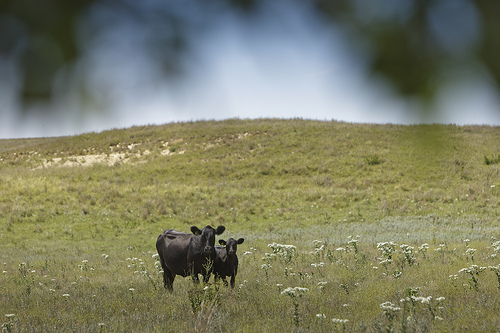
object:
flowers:
[377, 301, 394, 309]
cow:
[214, 237, 245, 290]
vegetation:
[0, 1, 500, 185]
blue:
[273, 6, 310, 27]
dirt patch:
[36, 150, 150, 170]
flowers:
[398, 242, 408, 248]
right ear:
[234, 237, 248, 246]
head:
[218, 237, 246, 257]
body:
[213, 244, 241, 277]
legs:
[219, 274, 230, 287]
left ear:
[188, 226, 202, 237]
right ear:
[214, 224, 226, 236]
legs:
[192, 274, 200, 286]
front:
[187, 224, 224, 289]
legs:
[162, 269, 177, 294]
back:
[154, 223, 184, 296]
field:
[0, 116, 500, 333]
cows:
[155, 224, 225, 293]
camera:
[0, 0, 497, 333]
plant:
[0, 231, 500, 333]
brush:
[365, 153, 383, 167]